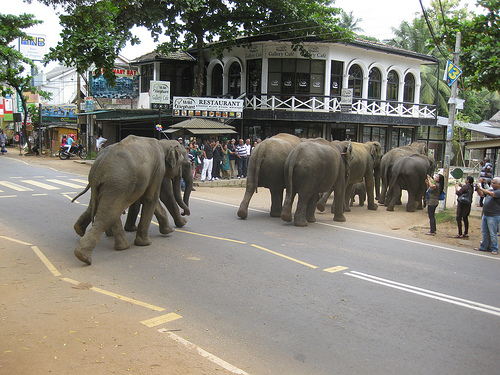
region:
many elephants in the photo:
[83, 126, 451, 257]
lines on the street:
[370, 262, 435, 332]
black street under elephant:
[260, 295, 327, 345]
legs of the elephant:
[85, 195, 196, 265]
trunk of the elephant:
[170, 171, 192, 221]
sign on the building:
[165, 90, 250, 125]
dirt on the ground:
[21, 310, 91, 370]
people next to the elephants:
[415, 166, 495, 216]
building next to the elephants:
[212, 16, 382, 126]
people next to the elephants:
[186, 129, 256, 168]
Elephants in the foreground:
[47, 111, 432, 266]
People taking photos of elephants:
[410, 160, 495, 246]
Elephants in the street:
[51, 121, 203, 263]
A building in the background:
[95, 20, 445, 160]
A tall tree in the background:
[395, 0, 497, 127]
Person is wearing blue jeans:
[470, 210, 495, 255]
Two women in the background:
[405, 165, 475, 245]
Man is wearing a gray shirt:
[473, 183, 496, 223]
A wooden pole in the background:
[441, 25, 462, 176]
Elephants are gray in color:
[58, 105, 440, 270]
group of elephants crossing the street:
[60, 131, 440, 268]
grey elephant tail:
[61, 168, 92, 205]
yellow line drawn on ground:
[190, 233, 316, 278]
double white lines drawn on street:
[348, 265, 499, 330]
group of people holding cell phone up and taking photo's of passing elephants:
[416, 161, 498, 251]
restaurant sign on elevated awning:
[173, 93, 245, 121]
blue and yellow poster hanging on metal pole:
[440, 56, 464, 88]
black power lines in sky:
[417, 0, 459, 65]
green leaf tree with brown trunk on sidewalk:
[2, 10, 39, 150]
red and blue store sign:
[82, 58, 146, 103]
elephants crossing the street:
[42, 22, 481, 328]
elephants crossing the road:
[78, 61, 437, 301]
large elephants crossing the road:
[65, 79, 492, 286]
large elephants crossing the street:
[32, 56, 483, 287]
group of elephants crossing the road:
[47, 58, 448, 286]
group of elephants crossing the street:
[52, 56, 478, 357]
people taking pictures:
[364, 119, 498, 293]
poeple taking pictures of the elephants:
[49, 63, 499, 320]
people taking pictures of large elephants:
[54, 29, 496, 305]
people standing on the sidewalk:
[386, 136, 497, 247]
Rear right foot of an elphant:
[68, 223, 113, 273]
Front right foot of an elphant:
[129, 222, 161, 253]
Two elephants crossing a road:
[231, 133, 359, 238]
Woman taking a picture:
[419, 170, 452, 237]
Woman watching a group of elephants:
[419, 170, 448, 242]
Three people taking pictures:
[418, 167, 498, 260]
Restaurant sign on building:
[169, 94, 247, 123]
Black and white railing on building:
[262, 85, 327, 117]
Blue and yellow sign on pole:
[438, 55, 466, 92]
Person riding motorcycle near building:
[54, 132, 92, 164]